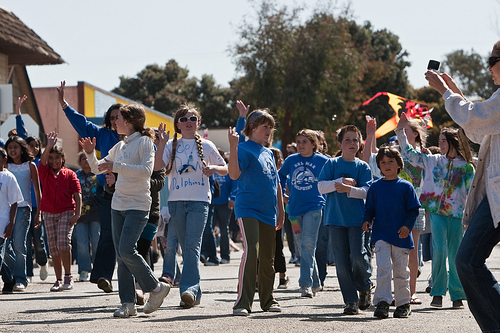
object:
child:
[77, 102, 173, 321]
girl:
[275, 125, 332, 299]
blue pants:
[286, 211, 322, 289]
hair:
[373, 146, 406, 178]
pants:
[231, 215, 278, 314]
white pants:
[369, 239, 413, 307]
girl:
[151, 104, 231, 309]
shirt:
[232, 138, 282, 227]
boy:
[358, 145, 422, 320]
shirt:
[36, 160, 83, 215]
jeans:
[166, 198, 208, 304]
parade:
[0, 38, 499, 332]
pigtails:
[193, 133, 207, 167]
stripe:
[230, 217, 249, 309]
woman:
[424, 39, 500, 332]